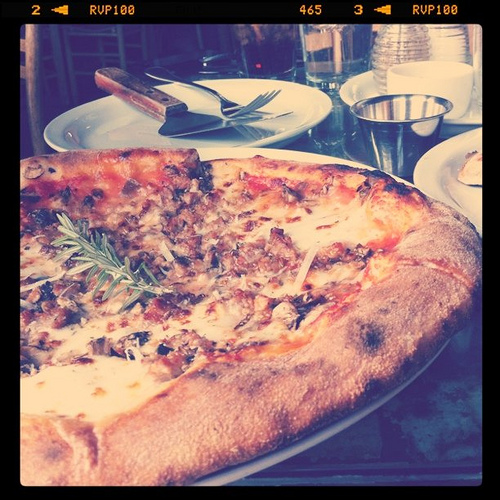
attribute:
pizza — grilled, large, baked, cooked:
[14, 143, 481, 496]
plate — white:
[83, 151, 481, 484]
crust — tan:
[254, 260, 481, 452]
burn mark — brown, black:
[346, 318, 397, 365]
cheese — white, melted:
[35, 360, 145, 414]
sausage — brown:
[174, 207, 293, 286]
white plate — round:
[45, 62, 331, 150]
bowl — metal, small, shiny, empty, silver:
[360, 90, 454, 176]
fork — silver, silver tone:
[144, 69, 299, 122]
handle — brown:
[86, 61, 192, 114]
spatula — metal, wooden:
[86, 65, 265, 140]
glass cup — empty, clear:
[291, 21, 367, 89]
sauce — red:
[36, 153, 161, 212]